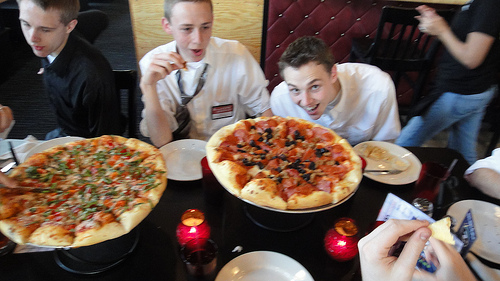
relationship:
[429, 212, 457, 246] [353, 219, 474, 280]
food in a hand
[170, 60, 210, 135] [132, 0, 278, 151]
neck tie on a man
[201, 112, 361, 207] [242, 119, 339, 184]
pizza with olive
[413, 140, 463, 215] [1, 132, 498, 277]
glass on dinner table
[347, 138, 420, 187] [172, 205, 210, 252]
plate between candle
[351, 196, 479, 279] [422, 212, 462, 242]
hands holding a bit of crust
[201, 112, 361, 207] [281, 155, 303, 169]
pizza with olives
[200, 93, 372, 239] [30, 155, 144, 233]
pizza with herbs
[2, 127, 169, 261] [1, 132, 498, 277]
pizza on table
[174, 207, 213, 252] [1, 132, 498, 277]
candle on table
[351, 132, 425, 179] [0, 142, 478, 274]
plate on table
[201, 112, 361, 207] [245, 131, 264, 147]
pizza covered in topping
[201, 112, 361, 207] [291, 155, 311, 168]
pizza covered in topping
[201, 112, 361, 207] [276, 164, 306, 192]
pizza covered in topping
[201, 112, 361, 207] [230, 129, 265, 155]
pizza covered in topping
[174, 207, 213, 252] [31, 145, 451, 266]
candle on a table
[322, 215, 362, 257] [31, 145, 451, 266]
candle on a table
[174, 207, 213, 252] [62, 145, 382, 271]
candle on a table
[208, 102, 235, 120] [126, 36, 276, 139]
name tag on a shirt